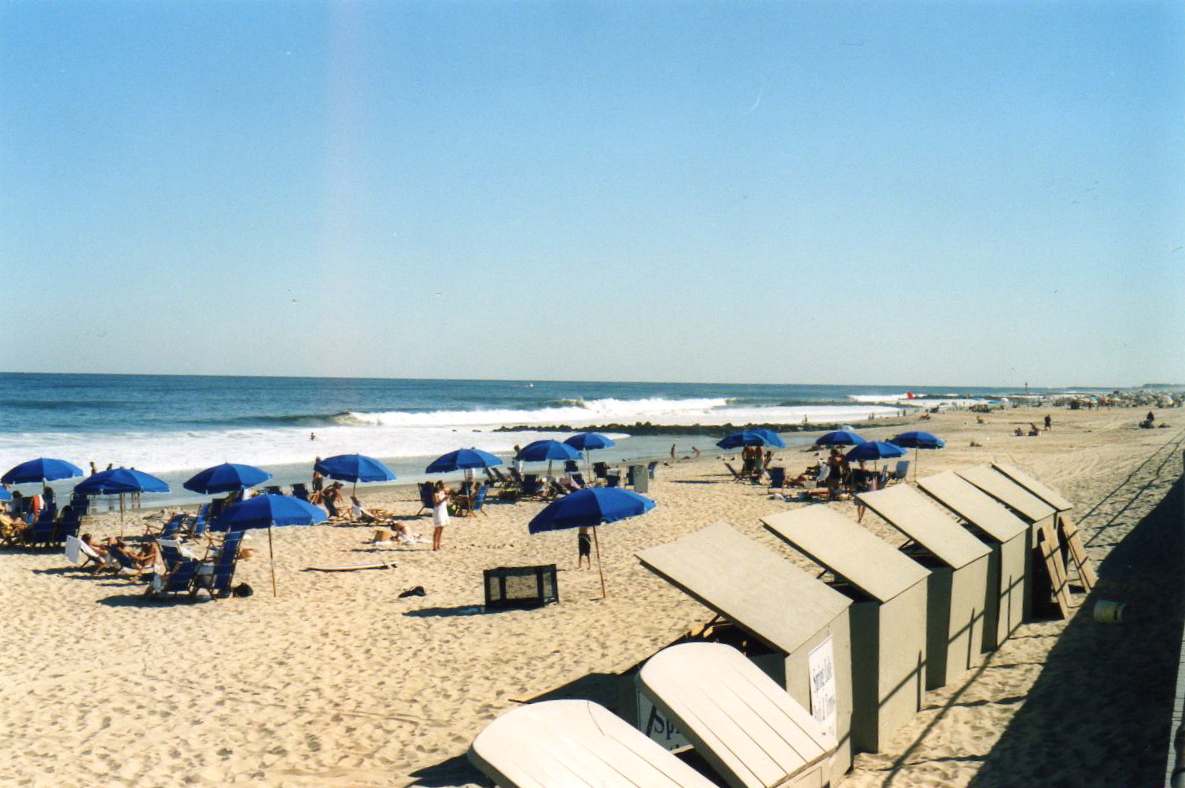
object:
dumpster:
[633, 514, 857, 748]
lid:
[635, 514, 855, 653]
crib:
[484, 564, 559, 607]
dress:
[433, 501, 449, 527]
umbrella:
[530, 487, 656, 599]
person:
[433, 480, 451, 551]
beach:
[2, 395, 1184, 786]